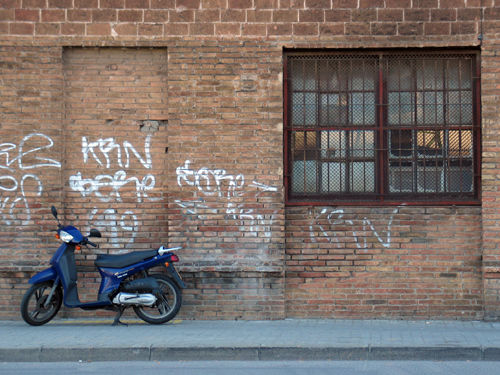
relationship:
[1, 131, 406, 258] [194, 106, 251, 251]
graffitti on wall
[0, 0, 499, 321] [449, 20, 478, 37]
brown wall on brick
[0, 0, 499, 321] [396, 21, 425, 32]
brown wall on brick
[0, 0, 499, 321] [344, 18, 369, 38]
brown wall on brick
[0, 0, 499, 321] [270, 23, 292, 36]
brown wall on brick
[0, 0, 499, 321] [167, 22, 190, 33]
brown wall on brick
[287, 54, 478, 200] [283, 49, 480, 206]
window has bars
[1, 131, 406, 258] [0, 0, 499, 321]
graffitti on brown wall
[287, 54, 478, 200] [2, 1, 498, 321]
window on building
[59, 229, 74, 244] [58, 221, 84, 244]
light on moped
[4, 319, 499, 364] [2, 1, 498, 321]
curb near building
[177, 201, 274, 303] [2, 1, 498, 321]
white paint on building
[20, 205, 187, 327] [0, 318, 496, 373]
bike on pavement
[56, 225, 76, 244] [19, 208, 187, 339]
light on bike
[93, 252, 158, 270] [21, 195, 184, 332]
seat on bike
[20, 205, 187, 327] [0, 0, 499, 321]
bike by brown wall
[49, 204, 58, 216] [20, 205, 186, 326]
mirror on moped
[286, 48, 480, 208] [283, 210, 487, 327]
mesh wire behind walls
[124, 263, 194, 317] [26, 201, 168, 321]
wheel of bike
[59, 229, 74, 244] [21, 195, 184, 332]
light of bike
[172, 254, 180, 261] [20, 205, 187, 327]
lights of bike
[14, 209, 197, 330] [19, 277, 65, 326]
bike has wheel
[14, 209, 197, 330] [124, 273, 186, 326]
bike has wheel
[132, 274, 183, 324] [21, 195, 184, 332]
wheel of a bike